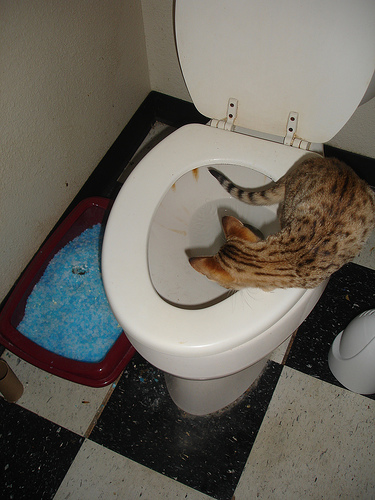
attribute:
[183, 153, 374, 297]
cat — tan, black, large, brown, laying, speckled, beige, dark, spotted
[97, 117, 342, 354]
seat — toilet, white, flipped up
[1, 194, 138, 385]
box — red, cat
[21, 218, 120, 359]
sand — blue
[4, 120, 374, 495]
linoleum — black, white, checkered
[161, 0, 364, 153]
lid — up, toilet, plastic, white, open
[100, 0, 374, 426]
toilet — dirty, porcelain, white, household, ceramic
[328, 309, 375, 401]
brush — toliet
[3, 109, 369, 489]
floor — tiled, cream, black, checkerboard, white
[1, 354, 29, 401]
roll — empty, toilet paper, paper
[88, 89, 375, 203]
molding — black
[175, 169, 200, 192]
stain — rust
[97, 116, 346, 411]
bowl — red, toilet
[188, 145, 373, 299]
animal — cat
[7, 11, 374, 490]
photo — indoors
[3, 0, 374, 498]
room — toilet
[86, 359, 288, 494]
tile — black, white, large, wrapped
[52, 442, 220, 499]
tile — white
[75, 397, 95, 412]
spot — black, small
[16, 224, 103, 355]
litter — shiny, blue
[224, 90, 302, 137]
screws — black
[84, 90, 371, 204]
edge — black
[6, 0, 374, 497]
bathroom — household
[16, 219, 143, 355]
liter — blue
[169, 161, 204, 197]
stains — rust